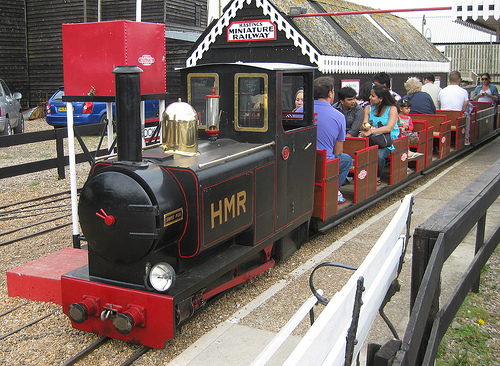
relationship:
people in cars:
[288, 68, 499, 204] [305, 103, 499, 233]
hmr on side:
[202, 190, 252, 230] [193, 111, 323, 250]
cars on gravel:
[0, 72, 163, 141] [1, 115, 499, 365]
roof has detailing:
[183, 0, 453, 66] [316, 53, 455, 74]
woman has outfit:
[364, 80, 402, 187] [365, 102, 399, 140]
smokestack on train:
[108, 62, 153, 162] [46, 17, 499, 321]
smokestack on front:
[108, 62, 153, 162] [46, 144, 200, 315]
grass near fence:
[428, 236, 497, 364] [357, 160, 498, 363]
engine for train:
[48, 52, 316, 346] [46, 17, 499, 321]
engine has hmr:
[48, 52, 316, 346] [210, 190, 247, 229]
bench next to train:
[232, 191, 415, 365] [46, 17, 499, 321]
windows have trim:
[184, 68, 271, 138] [182, 70, 275, 136]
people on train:
[288, 68, 499, 204] [46, 17, 499, 321]